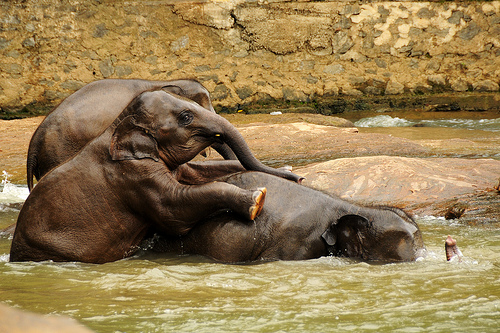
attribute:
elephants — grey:
[16, 63, 473, 275]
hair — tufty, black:
[305, 184, 425, 231]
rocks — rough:
[36, 7, 481, 81]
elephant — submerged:
[442, 231, 463, 263]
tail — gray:
[25, 124, 42, 193]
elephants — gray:
[8, 72, 428, 282]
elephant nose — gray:
[441, 233, 461, 256]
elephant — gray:
[195, 169, 451, 264]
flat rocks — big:
[1, 114, 498, 227]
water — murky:
[2, 110, 499, 330]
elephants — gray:
[7, 87, 303, 263]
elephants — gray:
[27, 76, 216, 192]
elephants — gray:
[137, 168, 427, 267]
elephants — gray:
[442, 234, 459, 263]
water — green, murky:
[2, 200, 494, 329]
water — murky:
[171, 277, 248, 288]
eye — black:
[178, 110, 193, 122]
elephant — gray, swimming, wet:
[23, 77, 237, 192]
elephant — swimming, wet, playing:
[8, 87, 303, 262]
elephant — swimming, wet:
[149, 167, 458, 264]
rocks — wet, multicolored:
[2, 2, 497, 128]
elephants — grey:
[109, 120, 453, 291]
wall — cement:
[91, 46, 498, 144]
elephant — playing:
[212, 170, 464, 266]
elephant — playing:
[27, 66, 220, 191]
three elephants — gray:
[9, 95, 306, 260]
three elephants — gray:
[5, 71, 241, 181]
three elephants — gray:
[140, 149, 463, 281]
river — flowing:
[9, 100, 491, 317]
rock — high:
[271, 115, 431, 198]